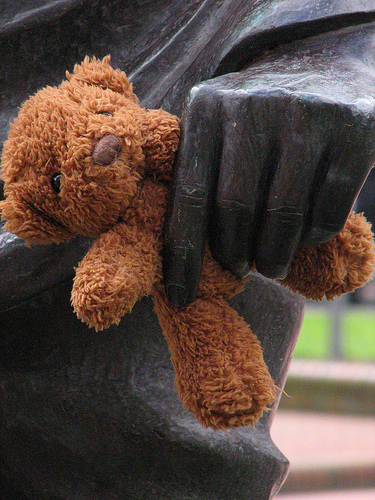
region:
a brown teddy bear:
[1, 53, 373, 432]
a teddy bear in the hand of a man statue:
[1, 52, 374, 431]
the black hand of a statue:
[163, 40, 374, 306]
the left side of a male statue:
[1, 1, 373, 498]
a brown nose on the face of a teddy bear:
[92, 135, 122, 165]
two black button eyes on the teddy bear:
[49, 107, 110, 189]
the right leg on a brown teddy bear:
[151, 306, 289, 428]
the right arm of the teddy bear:
[68, 234, 149, 331]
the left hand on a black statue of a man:
[163, 57, 372, 306]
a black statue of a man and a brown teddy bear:
[0, 50, 373, 498]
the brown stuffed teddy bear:
[0, 53, 373, 430]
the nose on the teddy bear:
[91, 133, 121, 165]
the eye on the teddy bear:
[51, 173, 60, 191]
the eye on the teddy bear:
[95, 109, 111, 116]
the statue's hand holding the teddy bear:
[163, 36, 374, 307]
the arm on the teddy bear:
[69, 221, 158, 331]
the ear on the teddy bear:
[1, 192, 75, 248]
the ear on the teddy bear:
[66, 53, 137, 101]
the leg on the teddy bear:
[278, 210, 373, 300]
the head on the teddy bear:
[0, 53, 151, 247]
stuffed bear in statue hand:
[5, 62, 370, 383]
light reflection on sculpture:
[204, 59, 373, 103]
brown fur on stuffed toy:
[4, 58, 364, 412]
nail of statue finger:
[166, 282, 190, 306]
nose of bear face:
[90, 132, 118, 165]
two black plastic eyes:
[48, 110, 113, 190]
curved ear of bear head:
[69, 52, 139, 99]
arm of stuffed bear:
[72, 232, 150, 322]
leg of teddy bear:
[151, 294, 275, 422]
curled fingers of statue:
[207, 224, 336, 283]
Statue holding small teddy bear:
[0, 0, 373, 499]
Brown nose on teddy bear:
[91, 134, 124, 164]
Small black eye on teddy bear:
[95, 105, 114, 118]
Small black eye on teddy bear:
[46, 165, 65, 188]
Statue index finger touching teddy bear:
[158, 84, 224, 310]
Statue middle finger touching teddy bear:
[210, 112, 266, 278]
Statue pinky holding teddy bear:
[302, 147, 371, 248]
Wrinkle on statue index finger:
[175, 180, 206, 196]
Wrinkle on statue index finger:
[173, 199, 207, 212]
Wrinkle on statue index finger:
[173, 188, 205, 203]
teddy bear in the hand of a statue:
[2, 11, 365, 433]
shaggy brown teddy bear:
[14, 61, 373, 432]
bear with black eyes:
[4, 49, 374, 441]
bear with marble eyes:
[17, 92, 142, 192]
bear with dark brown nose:
[0, 52, 168, 248]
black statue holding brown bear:
[2, 2, 368, 484]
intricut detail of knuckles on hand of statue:
[166, 143, 347, 239]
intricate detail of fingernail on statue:
[160, 225, 227, 320]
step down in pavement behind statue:
[281, 378, 369, 498]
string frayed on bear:
[179, 364, 311, 432]